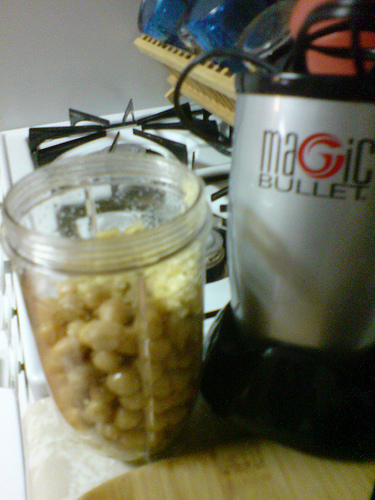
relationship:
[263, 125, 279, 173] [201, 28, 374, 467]
letter on appliance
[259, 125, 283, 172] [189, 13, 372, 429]
letter on appliance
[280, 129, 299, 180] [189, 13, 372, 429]
letter on appliance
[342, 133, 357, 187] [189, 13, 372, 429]
letter on appliance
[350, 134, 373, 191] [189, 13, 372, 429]
letter on appliance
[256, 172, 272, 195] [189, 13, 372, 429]
letter on appliance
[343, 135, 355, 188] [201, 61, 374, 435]
black letter on appliance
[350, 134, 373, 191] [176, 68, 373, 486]
letter on appliance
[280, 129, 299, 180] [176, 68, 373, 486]
letter on appliance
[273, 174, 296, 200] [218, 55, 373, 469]
letter on appliance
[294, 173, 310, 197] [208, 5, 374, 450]
letter on appliance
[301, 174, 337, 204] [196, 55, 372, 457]
letter on appliance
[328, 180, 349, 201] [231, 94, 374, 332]
letter on appliance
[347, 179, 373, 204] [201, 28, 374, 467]
letter on appliance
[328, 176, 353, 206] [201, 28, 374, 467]
letter on appliance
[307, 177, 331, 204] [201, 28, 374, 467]
letter on appliance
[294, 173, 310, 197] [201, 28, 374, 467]
letter on appliance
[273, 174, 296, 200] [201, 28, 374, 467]
letter on appliance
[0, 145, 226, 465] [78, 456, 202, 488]
container on counter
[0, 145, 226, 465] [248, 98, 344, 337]
container by bullet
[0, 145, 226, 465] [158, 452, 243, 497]
container on counter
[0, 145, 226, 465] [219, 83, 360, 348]
container by bullet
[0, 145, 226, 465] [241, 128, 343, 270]
container by bullet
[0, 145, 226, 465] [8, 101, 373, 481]
container on counter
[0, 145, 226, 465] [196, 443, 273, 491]
container on counter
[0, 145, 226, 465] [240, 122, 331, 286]
container by bullet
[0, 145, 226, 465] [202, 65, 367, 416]
container by bullet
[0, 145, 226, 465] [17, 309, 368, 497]
container on counter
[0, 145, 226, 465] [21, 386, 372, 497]
container on counter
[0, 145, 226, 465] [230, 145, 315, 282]
container by bullet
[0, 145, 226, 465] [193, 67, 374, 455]
container by bullet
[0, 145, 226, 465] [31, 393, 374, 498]
container on counter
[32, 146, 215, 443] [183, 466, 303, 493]
container on counter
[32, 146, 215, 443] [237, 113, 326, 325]
container by bullet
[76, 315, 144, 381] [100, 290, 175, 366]
corn in cup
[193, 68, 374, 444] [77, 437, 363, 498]
magic bullet on table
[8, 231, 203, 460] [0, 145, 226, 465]
corn kernels in container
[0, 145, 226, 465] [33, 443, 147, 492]
container on board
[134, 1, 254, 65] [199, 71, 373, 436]
blue cups behind juicer